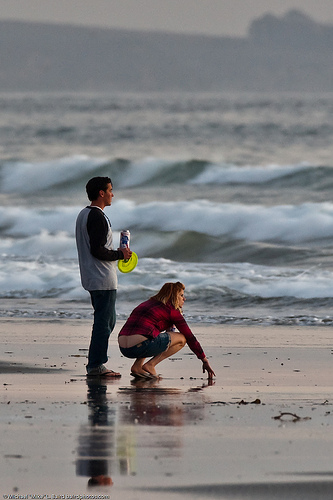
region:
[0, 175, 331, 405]
two people on a shore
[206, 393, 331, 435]
debris on shore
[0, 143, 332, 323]
waves rolling in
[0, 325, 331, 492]
sand is wet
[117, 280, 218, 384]
woman crouching on the sand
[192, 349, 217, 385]
woman's fingertips touching the sand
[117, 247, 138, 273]
man holding a yellow disk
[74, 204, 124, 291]
man is wearing a loose fitting black and grey shirt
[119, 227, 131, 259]
man is holding a large container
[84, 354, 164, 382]
man and woman are both wearing flip-flops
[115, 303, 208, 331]
girl wearing red blouse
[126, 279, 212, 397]
girl looking to her right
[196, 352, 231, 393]
hand touching the water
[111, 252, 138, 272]
a yellow disc is held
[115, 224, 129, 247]
beverage being held by man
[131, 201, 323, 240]
water caps are white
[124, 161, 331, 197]
waves of the ocean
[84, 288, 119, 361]
man wearing dark pants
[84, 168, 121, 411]
person looking out at ocean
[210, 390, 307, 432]
items on the beach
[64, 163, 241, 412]
a man and woman on the beach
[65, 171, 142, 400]
a man standing on the beach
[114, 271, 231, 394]
a woman squatting on the beach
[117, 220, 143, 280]
a man holding a beer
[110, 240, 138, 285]
a man holding a frisbee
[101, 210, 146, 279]
a man holding a beer and a frisbee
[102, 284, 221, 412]
a woman wearin a plaid shirt and shorts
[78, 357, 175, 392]
people wearing flip flops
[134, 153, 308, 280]
waves in the ocean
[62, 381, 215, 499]
reflection on the wet sand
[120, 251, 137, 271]
yellow frisbee in hand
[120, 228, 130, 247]
can of beer in hand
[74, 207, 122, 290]
black and grey shirt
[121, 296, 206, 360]
red and black shirt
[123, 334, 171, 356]
darb blue denim shorts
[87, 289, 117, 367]
medium blue denim jeans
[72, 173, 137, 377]
man standing in sand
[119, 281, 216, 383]
woman looking at ocean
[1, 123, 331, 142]
wave forming in ocean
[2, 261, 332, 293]
white foam in ocean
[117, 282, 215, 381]
woman with shorts not pulled up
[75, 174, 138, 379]
man standing holding yellow frisbee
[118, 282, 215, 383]
woman wearing red shirt squatting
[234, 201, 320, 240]
large white waves crashing against the beach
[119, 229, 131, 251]
man holding red white and blue beer can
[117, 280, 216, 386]
woman in red touching the sand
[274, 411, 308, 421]
debris washed onto the sand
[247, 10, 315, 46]
black storm clouds in the distance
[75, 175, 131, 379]
man standing on beach wearing black sandals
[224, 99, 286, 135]
rough blue ocean behind the waves